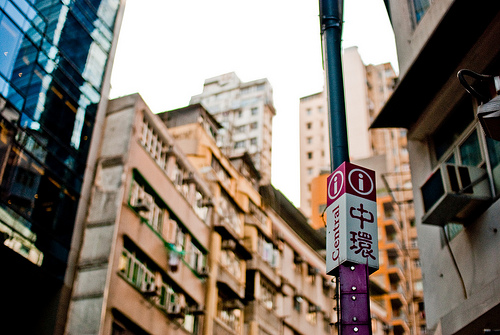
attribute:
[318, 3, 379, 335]
pole — black, fuschia, metallic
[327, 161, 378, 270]
sign — white, fushcia, red, pink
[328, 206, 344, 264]
central — red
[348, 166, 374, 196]
circle — white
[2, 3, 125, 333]
building — tall, high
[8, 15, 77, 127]
windows — closed, shiny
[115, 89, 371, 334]
building — brown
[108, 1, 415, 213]
sky — white, bright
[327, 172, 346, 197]
symbol — information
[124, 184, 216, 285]
strip — green